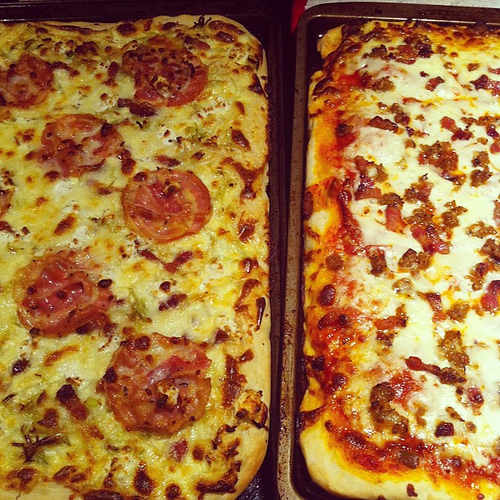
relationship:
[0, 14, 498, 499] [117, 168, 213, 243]
pizza with piece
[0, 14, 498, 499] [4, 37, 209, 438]
pizza with toppings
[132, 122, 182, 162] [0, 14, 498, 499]
cheese on top of pizza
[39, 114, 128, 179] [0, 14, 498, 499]
pepperoni on top of pizza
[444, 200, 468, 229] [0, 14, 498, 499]
sausage on top of pizza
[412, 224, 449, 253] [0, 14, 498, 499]
ham on top of pizza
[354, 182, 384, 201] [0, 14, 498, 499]
bacon on top of pizza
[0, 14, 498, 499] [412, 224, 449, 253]
pizza with ham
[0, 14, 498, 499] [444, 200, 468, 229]
pizza with sausage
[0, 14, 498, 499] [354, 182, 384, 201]
pizza with bacon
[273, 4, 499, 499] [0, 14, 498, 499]
pan under pizza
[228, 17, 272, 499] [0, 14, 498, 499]
crust on pizza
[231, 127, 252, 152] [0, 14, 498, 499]
spot on pizza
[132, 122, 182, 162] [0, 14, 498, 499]
cheese on pizza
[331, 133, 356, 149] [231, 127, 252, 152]
tomato sauce spot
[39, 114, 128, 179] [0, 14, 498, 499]
pepperoni on pizza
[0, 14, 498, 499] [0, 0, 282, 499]
pizza on left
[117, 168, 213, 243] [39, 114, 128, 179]
piece of pepperoni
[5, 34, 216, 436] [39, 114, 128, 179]
pieces of pepperoni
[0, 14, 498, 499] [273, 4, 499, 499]
pizza in pan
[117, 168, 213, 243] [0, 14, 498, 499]
piece of pizza